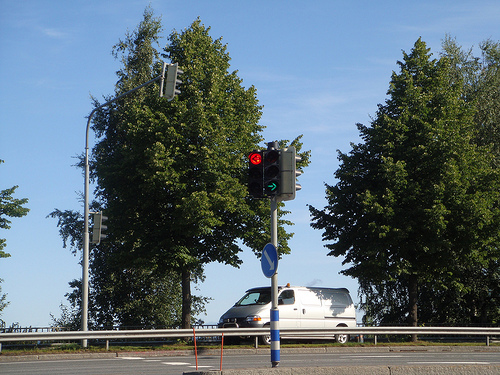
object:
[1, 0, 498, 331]
blue sky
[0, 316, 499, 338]
barrier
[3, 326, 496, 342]
metal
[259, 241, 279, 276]
sign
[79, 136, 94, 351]
pole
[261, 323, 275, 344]
tire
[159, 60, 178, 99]
traffic light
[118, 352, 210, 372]
white lines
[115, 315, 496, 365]
lines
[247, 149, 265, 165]
light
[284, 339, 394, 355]
curb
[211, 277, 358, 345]
van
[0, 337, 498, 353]
grass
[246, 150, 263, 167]
traffic light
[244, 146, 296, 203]
traffic light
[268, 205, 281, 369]
pole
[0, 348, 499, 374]
ashphalt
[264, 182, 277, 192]
arrow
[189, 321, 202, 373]
stick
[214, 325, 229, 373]
stick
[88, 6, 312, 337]
tree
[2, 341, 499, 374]
road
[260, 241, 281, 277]
arrow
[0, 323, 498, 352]
rail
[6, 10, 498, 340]
distance